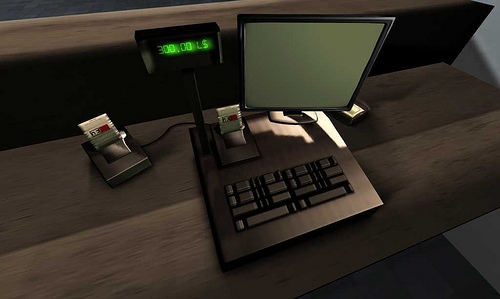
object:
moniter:
[234, 12, 392, 112]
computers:
[189, 8, 393, 267]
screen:
[242, 23, 382, 107]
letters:
[157, 46, 165, 55]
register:
[76, 14, 397, 273]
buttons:
[234, 220, 245, 232]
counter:
[0, 60, 498, 299]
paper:
[78, 113, 120, 148]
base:
[194, 112, 385, 272]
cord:
[140, 121, 196, 146]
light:
[257, 112, 345, 143]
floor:
[311, 230, 500, 299]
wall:
[451, 2, 500, 86]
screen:
[157, 39, 214, 58]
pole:
[175, 68, 213, 155]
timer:
[87, 124, 111, 139]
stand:
[267, 109, 318, 125]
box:
[80, 130, 151, 187]